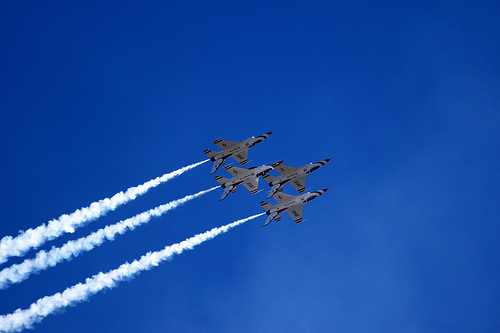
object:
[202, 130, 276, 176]
plane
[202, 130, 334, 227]
formation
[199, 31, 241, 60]
sky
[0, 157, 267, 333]
smoke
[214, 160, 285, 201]
plane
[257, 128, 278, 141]
nose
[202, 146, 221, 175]
tail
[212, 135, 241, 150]
wing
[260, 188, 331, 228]
plane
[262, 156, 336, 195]
plane